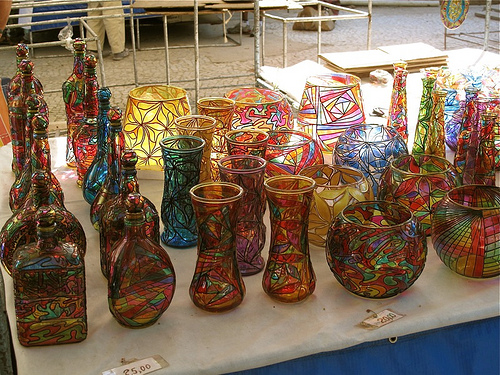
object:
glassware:
[431, 184, 500, 279]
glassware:
[377, 154, 464, 237]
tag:
[354, 308, 405, 331]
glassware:
[299, 164, 375, 248]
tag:
[101, 354, 172, 375]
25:
[122, 367, 138, 373]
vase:
[330, 124, 408, 199]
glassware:
[89, 108, 127, 232]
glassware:
[218, 154, 267, 276]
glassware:
[189, 178, 244, 310]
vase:
[325, 200, 429, 301]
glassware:
[295, 73, 367, 155]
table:
[185, 319, 270, 344]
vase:
[261, 129, 325, 183]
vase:
[224, 88, 294, 132]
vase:
[174, 114, 218, 182]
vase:
[61, 39, 89, 167]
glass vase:
[187, 181, 247, 314]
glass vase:
[262, 173, 318, 305]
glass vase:
[0, 171, 86, 279]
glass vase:
[11, 207, 87, 348]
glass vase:
[99, 150, 160, 279]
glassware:
[82, 87, 119, 205]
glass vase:
[106, 193, 176, 330]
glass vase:
[125, 83, 192, 170]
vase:
[410, 78, 436, 154]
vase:
[386, 60, 409, 147]